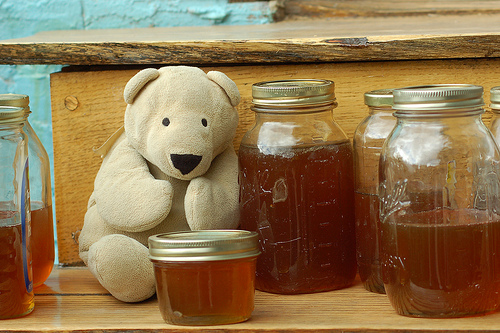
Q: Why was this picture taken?
A: For a magazine.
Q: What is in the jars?
A: Honey.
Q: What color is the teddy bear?
A: Beige.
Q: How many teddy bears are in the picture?
A: One.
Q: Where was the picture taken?
A: A front porch.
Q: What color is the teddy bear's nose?
A: Black.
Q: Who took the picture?
A: The owner.